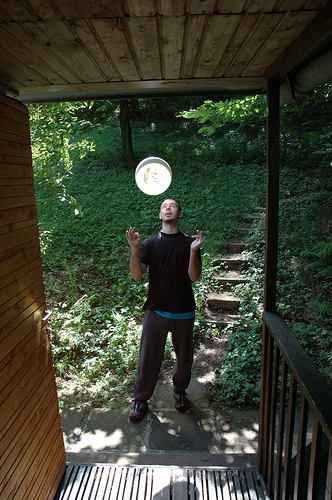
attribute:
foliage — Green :
[91, 194, 111, 228]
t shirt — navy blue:
[135, 231, 197, 306]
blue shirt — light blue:
[154, 303, 199, 321]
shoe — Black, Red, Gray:
[127, 398, 149, 425]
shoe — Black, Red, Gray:
[172, 388, 190, 412]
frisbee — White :
[133, 151, 172, 198]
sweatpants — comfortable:
[130, 311, 193, 404]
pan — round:
[133, 152, 175, 199]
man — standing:
[118, 196, 211, 426]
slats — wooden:
[65, 463, 88, 499]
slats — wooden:
[82, 465, 98, 499]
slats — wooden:
[94, 463, 111, 498]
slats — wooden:
[151, 467, 172, 499]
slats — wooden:
[206, 470, 216, 499]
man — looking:
[135, 179, 234, 435]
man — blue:
[112, 194, 226, 429]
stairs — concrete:
[189, 178, 283, 372]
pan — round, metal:
[113, 147, 188, 203]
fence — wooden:
[243, 301, 330, 499]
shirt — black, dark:
[137, 230, 202, 313]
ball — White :
[125, 145, 183, 195]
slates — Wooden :
[194, 203, 270, 331]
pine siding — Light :
[1, 116, 30, 325]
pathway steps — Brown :
[194, 163, 296, 387]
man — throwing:
[126, 199, 208, 422]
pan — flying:
[131, 154, 173, 198]